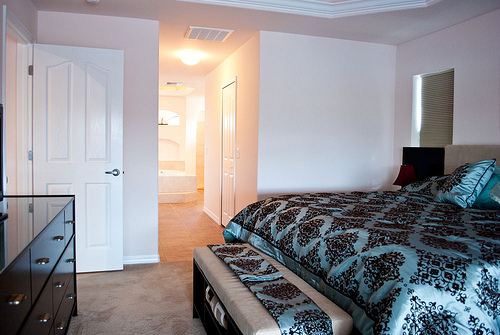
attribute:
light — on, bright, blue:
[171, 47, 204, 70]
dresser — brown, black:
[37, 194, 102, 295]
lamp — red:
[399, 165, 416, 186]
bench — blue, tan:
[180, 240, 292, 329]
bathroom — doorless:
[158, 117, 205, 195]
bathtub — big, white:
[155, 162, 196, 197]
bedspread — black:
[364, 260, 456, 312]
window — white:
[415, 80, 456, 123]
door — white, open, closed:
[35, 44, 129, 237]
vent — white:
[179, 19, 240, 50]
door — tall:
[208, 82, 248, 201]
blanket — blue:
[297, 177, 379, 270]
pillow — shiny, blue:
[440, 163, 493, 210]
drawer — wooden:
[49, 218, 80, 266]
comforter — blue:
[408, 222, 472, 277]